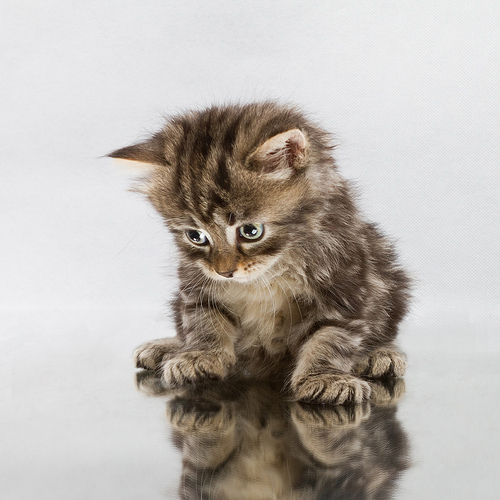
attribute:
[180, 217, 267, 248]
eyes — blue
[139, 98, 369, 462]
cat — white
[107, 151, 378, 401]
cat — black, brown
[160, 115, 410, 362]
fur — brown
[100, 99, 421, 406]
cat — looking down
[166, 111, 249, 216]
stripes — black